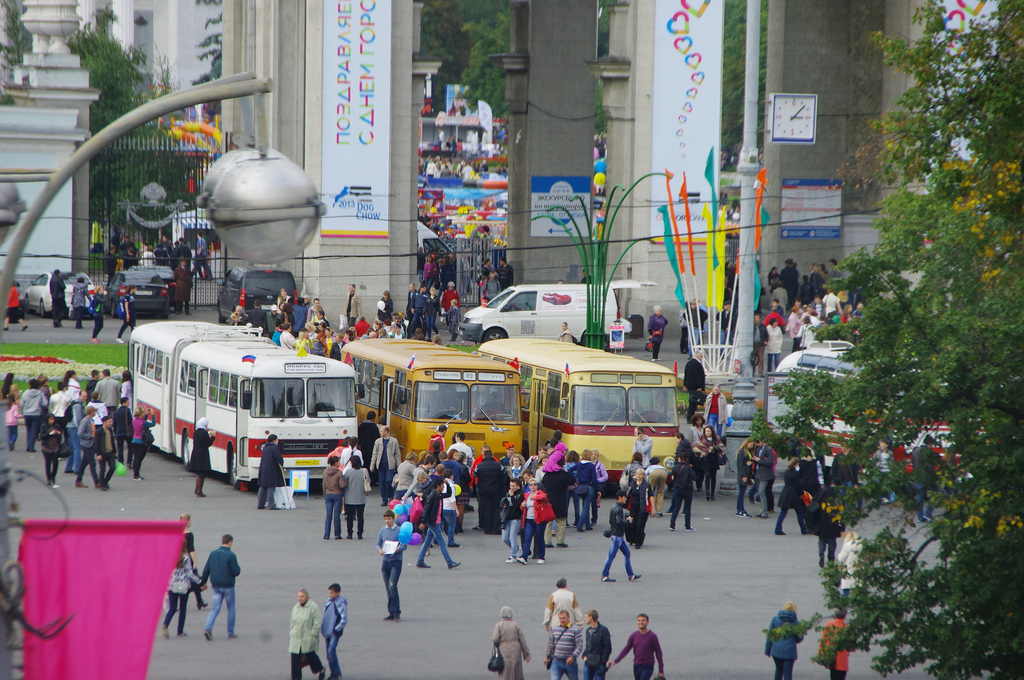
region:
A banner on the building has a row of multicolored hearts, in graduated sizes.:
[666, 9, 704, 168]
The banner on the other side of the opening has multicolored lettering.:
[337, 7, 376, 147]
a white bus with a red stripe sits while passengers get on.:
[129, 320, 360, 489]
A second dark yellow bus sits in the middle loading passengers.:
[341, 335, 531, 491]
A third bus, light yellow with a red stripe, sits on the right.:
[479, 335, 683, 473]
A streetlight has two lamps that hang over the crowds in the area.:
[6, 70, 329, 267]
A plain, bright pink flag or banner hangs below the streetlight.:
[21, 518, 195, 677]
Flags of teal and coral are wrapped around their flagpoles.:
[657, 145, 772, 371]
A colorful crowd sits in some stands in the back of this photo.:
[413, 85, 508, 231]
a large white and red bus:
[119, 310, 360, 495]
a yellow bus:
[333, 328, 526, 487]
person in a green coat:
[283, 581, 329, 674]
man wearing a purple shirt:
[614, 612, 666, 677]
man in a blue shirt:
[373, 509, 418, 620]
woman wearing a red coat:
[520, 473, 556, 562]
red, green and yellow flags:
[650, 143, 772, 382]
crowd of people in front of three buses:
[119, 312, 695, 584]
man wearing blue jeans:
[196, 533, 251, 642]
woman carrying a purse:
[484, 601, 539, 677]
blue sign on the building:
[782, 170, 847, 247]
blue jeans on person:
[596, 528, 636, 577]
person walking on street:
[600, 502, 643, 579]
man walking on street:
[615, 613, 677, 677]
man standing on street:
[369, 509, 415, 624]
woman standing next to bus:
[180, 416, 232, 497]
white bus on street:
[116, 300, 366, 507]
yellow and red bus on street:
[486, 329, 717, 489]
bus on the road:
[125, 317, 356, 492]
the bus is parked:
[348, 333, 526, 492]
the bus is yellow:
[476, 340, 677, 484]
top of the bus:
[134, 322, 350, 374]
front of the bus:
[402, 368, 523, 471]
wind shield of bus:
[576, 387, 675, 425]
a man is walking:
[289, 586, 327, 676]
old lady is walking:
[485, 603, 531, 676]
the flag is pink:
[20, 521, 192, 676]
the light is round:
[209, 141, 327, 266]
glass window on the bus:
[301, 365, 353, 413]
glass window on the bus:
[248, 375, 309, 421]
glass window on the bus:
[411, 381, 473, 426]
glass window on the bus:
[462, 378, 511, 420]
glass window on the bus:
[570, 381, 625, 420]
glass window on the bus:
[620, 384, 674, 423]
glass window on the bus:
[542, 381, 555, 414]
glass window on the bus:
[206, 367, 229, 406]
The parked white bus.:
[123, 304, 352, 491]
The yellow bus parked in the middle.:
[344, 333, 518, 476]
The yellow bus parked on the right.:
[501, 331, 672, 483]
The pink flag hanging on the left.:
[9, 513, 169, 675]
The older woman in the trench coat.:
[480, 600, 542, 677]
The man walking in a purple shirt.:
[618, 610, 667, 675]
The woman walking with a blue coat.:
[762, 595, 802, 673]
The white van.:
[465, 269, 621, 371]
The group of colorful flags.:
[654, 143, 790, 404]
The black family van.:
[223, 265, 303, 339]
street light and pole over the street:
[0, 62, 326, 293]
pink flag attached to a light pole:
[2, 512, 192, 672]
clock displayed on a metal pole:
[736, 0, 826, 191]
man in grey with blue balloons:
[373, 508, 421, 626]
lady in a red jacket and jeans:
[515, 476, 558, 565]